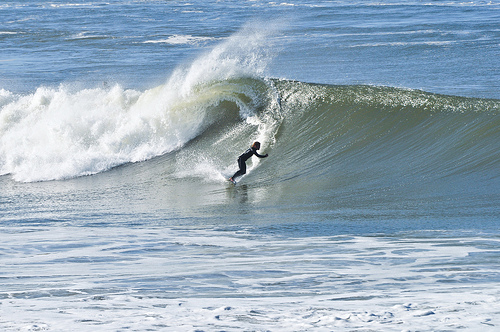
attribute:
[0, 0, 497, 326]
water — calm, ocean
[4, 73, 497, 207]
waves — white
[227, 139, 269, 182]
surfer — distant, leaning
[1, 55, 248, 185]
foam — white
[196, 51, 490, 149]
wave — section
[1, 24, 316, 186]
foam — created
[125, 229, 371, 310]
water — foam, surface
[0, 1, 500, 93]
water — calm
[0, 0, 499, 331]
ocean water — large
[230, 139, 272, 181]
person — riding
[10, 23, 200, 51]
caps — white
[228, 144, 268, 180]
surfer — wearing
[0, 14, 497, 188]
wave — middle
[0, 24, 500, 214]
wave — white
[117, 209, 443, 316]
water — part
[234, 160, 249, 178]
knees — bent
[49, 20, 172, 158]
ocean — part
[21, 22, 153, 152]
water — white